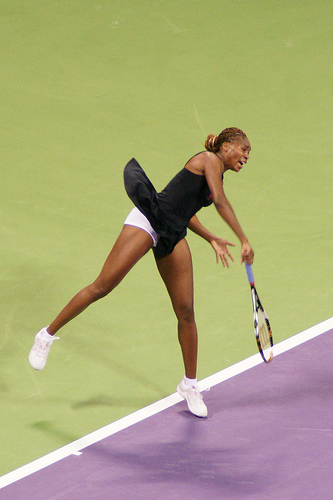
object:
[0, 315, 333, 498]
court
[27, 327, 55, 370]
shoe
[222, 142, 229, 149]
ear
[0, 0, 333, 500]
ground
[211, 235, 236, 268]
hand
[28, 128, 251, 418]
person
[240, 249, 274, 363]
racket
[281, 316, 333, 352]
paint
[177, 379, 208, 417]
shoe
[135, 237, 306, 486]
line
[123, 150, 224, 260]
black dress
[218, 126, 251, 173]
head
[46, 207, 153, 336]
leg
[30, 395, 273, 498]
shadow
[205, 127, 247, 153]
hair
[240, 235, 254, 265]
hand